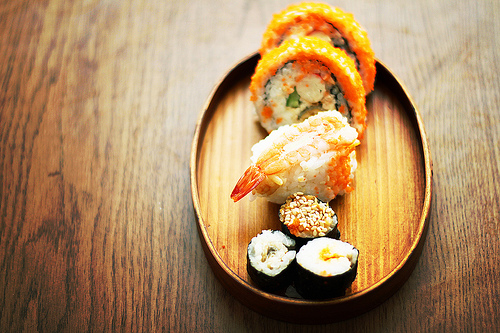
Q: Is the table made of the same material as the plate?
A: Yes, both the table and the plate are made of wood.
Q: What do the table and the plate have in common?
A: The material, both the table and the plate are wooden.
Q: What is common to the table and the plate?
A: The material, both the table and the plate are wooden.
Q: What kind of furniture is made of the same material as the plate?
A: The table is made of the same material as the plate.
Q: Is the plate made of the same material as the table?
A: Yes, both the plate and the table are made of wood.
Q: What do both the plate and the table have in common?
A: The material, both the plate and the table are wooden.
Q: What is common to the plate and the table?
A: The material, both the plate and the table are wooden.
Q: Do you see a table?
A: Yes, there is a table.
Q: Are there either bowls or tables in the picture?
A: Yes, there is a table.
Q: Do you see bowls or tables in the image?
A: Yes, there is a table.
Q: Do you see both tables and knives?
A: No, there is a table but no knives.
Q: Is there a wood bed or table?
A: Yes, there is a wood table.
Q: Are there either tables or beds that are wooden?
A: Yes, the table is wooden.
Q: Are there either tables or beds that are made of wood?
A: Yes, the table is made of wood.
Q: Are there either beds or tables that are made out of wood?
A: Yes, the table is made of wood.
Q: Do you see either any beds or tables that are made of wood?
A: Yes, the table is made of wood.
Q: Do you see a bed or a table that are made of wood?
A: Yes, the table is made of wood.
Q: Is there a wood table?
A: Yes, there is a wood table.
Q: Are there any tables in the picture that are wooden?
A: Yes, there is a table that is wooden.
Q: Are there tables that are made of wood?
A: Yes, there is a table that is made of wood.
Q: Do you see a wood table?
A: Yes, there is a table that is made of wood.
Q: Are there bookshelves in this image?
A: No, there are no bookshelves.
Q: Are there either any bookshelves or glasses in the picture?
A: No, there are no bookshelves or glasses.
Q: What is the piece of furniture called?
A: The piece of furniture is a table.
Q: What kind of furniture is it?
A: The piece of furniture is a table.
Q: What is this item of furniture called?
A: This is a table.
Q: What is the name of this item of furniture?
A: This is a table.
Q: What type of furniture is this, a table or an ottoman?
A: This is a table.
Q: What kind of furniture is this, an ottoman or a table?
A: This is a table.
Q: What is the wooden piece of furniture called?
A: The piece of furniture is a table.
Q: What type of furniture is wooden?
A: The furniture is a table.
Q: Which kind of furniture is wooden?
A: The furniture is a table.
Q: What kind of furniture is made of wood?
A: The furniture is a table.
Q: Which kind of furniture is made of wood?
A: The furniture is a table.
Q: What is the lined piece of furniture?
A: The piece of furniture is a table.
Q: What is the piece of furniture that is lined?
A: The piece of furniture is a table.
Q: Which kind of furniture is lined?
A: The furniture is a table.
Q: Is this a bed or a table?
A: This is a table.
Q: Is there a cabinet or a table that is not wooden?
A: No, there is a table but it is wooden.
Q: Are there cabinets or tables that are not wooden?
A: No, there is a table but it is wooden.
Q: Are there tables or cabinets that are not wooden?
A: No, there is a table but it is wooden.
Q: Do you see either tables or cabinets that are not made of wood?
A: No, there is a table but it is made of wood.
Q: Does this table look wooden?
A: Yes, the table is wooden.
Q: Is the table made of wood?
A: Yes, the table is made of wood.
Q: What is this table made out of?
A: The table is made of wood.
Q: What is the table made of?
A: The table is made of wood.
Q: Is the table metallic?
A: No, the table is wooden.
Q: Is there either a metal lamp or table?
A: No, there is a table but it is wooden.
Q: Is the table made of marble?
A: No, the table is made of wood.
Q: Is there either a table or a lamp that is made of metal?
A: No, there is a table but it is made of wood.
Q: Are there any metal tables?
A: No, there is a table but it is made of wood.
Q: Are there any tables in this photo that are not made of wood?
A: No, there is a table but it is made of wood.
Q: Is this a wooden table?
A: Yes, this is a wooden table.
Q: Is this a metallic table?
A: No, this is a wooden table.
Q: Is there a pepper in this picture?
A: No, there are no peppers.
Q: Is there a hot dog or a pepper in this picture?
A: No, there are no peppers or hot dogs.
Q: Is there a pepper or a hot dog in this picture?
A: No, there are no peppers or hot dogs.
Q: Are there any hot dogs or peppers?
A: No, there are no peppers or hot dogs.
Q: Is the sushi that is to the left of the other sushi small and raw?
A: Yes, the sushi is small and raw.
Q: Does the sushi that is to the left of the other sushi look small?
A: Yes, the sushi is small.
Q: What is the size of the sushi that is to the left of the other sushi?
A: The sushi is small.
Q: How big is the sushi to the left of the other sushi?
A: The sushi is small.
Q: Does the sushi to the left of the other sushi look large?
A: No, the sushi is small.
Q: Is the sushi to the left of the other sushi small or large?
A: The sushi is small.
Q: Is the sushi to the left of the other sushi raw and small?
A: Yes, the sushi is raw and small.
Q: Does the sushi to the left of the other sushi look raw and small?
A: Yes, the sushi is raw and small.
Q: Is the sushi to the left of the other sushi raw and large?
A: No, the sushi is raw but small.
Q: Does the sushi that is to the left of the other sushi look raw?
A: Yes, the sushi is raw.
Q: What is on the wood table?
A: The sushi is on the table.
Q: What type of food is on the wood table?
A: The food is sushi.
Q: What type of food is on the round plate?
A: The food is sushi.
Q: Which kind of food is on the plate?
A: The food is sushi.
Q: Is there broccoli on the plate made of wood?
A: No, there is sushi on the plate.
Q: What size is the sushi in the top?
A: The sushi is large.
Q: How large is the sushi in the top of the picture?
A: The sushi is large.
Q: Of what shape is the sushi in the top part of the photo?
A: The sushi is round.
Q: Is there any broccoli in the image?
A: No, there is no broccoli.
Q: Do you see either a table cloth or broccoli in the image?
A: No, there are no broccoli or tablecloths.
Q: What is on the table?
A: The sushi is on the table.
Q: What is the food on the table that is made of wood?
A: The food is sushi.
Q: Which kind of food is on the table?
A: The food is sushi.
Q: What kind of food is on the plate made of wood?
A: The food is sushi.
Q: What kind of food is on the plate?
A: The food is sushi.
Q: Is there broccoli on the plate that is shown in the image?
A: No, there is sushi on the plate.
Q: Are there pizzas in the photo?
A: No, there are no pizzas.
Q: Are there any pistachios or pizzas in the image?
A: No, there are no pizzas or pistachios.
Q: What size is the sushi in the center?
A: The sushi is large.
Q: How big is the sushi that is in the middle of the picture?
A: The sushi is large.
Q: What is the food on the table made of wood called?
A: The food is sushi.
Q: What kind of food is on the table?
A: The food is sushi.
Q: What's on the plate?
A: The sushi is on the plate.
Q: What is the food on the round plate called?
A: The food is sushi.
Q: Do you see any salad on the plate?
A: No, there is sushi on the plate.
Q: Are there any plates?
A: Yes, there is a plate.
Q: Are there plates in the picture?
A: Yes, there is a plate.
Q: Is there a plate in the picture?
A: Yes, there is a plate.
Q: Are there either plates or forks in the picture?
A: Yes, there is a plate.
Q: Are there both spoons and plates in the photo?
A: No, there is a plate but no spoons.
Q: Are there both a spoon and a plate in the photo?
A: No, there is a plate but no spoons.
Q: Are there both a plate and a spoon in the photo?
A: No, there is a plate but no spoons.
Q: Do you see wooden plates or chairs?
A: Yes, there is a wood plate.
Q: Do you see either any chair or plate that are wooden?
A: Yes, the plate is wooden.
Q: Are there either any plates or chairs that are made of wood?
A: Yes, the plate is made of wood.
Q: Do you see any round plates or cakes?
A: Yes, there is a round plate.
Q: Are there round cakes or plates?
A: Yes, there is a round plate.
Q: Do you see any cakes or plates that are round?
A: Yes, the plate is round.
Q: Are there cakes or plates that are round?
A: Yes, the plate is round.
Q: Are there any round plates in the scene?
A: Yes, there is a round plate.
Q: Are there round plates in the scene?
A: Yes, there is a round plate.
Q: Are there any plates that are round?
A: Yes, there is a plate that is round.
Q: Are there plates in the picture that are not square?
A: Yes, there is a round plate.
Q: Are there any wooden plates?
A: Yes, there is a wood plate.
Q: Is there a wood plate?
A: Yes, there is a wood plate.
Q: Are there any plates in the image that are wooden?
A: Yes, there is a plate that is wooden.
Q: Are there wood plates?
A: Yes, there is a plate that is made of wood.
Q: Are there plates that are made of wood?
A: Yes, there is a plate that is made of wood.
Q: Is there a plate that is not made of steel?
A: Yes, there is a plate that is made of wood.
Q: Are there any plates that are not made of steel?
A: Yes, there is a plate that is made of wood.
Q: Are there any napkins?
A: No, there are no napkins.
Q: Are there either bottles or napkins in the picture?
A: No, there are no napkins or bottles.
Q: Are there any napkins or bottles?
A: No, there are no napkins or bottles.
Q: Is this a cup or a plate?
A: This is a plate.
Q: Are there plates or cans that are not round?
A: No, there is a plate but it is round.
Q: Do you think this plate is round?
A: Yes, the plate is round.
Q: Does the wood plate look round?
A: Yes, the plate is round.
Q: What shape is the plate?
A: The plate is round.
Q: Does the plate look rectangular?
A: No, the plate is round.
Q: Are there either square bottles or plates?
A: No, there is a plate but it is round.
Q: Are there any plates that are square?
A: No, there is a plate but it is round.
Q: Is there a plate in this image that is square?
A: No, there is a plate but it is round.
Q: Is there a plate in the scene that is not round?
A: No, there is a plate but it is round.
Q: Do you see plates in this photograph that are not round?
A: No, there is a plate but it is round.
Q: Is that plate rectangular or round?
A: The plate is round.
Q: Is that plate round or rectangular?
A: The plate is round.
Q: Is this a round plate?
A: Yes, this is a round plate.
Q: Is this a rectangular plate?
A: No, this is a round plate.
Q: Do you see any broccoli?
A: No, there is no broccoli.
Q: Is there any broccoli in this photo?
A: No, there is no broccoli.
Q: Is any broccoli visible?
A: No, there is no broccoli.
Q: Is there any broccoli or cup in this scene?
A: No, there are no broccoli or cups.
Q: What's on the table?
A: The sushi is on the table.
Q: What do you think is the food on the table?
A: The food is sushi.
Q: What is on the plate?
A: The sushi is on the plate.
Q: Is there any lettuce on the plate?
A: No, there is sushi on the plate.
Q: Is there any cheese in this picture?
A: No, there is no cheese.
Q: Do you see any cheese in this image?
A: No, there is no cheese.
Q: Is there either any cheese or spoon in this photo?
A: No, there are no cheese or spoons.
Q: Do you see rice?
A: Yes, there is rice.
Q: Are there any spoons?
A: No, there are no spoons.